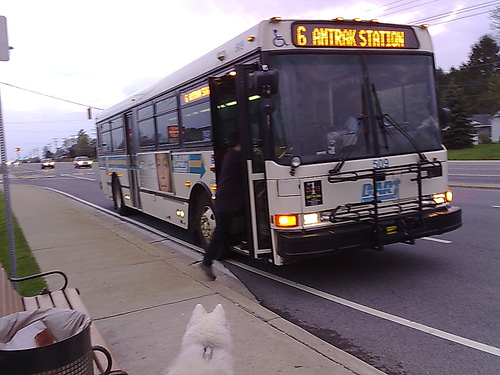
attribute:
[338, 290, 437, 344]
line — white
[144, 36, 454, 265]
person — entering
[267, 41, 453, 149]
windshield — wide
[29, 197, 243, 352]
sidewalk — paved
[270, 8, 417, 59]
words — golden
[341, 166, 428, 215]
logo — blue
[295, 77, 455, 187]
wipers — black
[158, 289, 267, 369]
dog — white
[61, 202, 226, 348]
sidewalk — paved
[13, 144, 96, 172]
cars — moving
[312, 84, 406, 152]
man — driving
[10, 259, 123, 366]
bench — brown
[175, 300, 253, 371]
dog — white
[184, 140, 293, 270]
man — entering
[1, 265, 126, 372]
bench — brown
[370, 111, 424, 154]
windshield wipers — black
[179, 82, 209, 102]
light — bright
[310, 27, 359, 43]
light — bright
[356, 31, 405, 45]
light — bright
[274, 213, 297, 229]
light — bright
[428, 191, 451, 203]
light — bright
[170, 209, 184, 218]
light — bright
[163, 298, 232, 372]
dog — white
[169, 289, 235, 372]
dog — white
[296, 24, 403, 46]
letters — yellow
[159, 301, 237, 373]
dog — white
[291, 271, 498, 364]
line — white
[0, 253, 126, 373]
bench — wood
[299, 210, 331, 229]
head light — white lit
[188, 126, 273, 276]
passenger — getting on